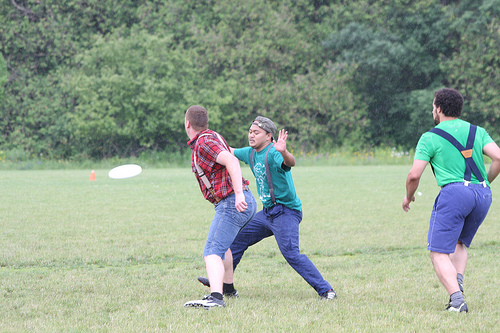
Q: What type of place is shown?
A: It is a field.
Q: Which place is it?
A: It is a field.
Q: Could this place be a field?
A: Yes, it is a field.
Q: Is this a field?
A: Yes, it is a field.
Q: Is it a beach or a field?
A: It is a field.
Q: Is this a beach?
A: No, it is a field.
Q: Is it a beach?
A: No, it is a field.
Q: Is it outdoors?
A: Yes, it is outdoors.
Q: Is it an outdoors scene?
A: Yes, it is outdoors.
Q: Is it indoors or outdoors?
A: It is outdoors.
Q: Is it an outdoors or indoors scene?
A: It is outdoors.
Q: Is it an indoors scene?
A: No, it is outdoors.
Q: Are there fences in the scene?
A: No, there are no fences.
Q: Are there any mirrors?
A: No, there are no mirrors.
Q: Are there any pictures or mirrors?
A: No, there are no mirrors or pictures.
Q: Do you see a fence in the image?
A: No, there are no fences.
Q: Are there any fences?
A: No, there are no fences.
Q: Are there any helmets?
A: No, there are no helmets.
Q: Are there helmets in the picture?
A: No, there are no helmets.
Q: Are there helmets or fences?
A: No, there are no helmets or fences.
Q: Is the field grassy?
A: Yes, the field is grassy.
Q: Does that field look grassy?
A: Yes, the field is grassy.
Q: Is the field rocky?
A: No, the field is grassy.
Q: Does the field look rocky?
A: No, the field is grassy.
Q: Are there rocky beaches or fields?
A: No, there is a field but it is grassy.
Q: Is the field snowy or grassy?
A: The field is grassy.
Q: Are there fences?
A: No, there are no fences.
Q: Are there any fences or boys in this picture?
A: No, there are no fences or boys.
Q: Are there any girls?
A: No, there are no girls.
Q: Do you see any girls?
A: No, there are no girls.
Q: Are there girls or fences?
A: No, there are no girls or fences.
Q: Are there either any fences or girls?
A: No, there are no girls or fences.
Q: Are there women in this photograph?
A: No, there are no women.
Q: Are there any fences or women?
A: No, there are no women or fences.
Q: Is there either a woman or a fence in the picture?
A: No, there are no women or fences.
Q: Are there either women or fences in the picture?
A: No, there are no women or fences.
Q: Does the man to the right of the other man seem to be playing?
A: Yes, the man is playing.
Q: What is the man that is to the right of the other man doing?
A: The man is playing.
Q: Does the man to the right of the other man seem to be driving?
A: No, the man is playing.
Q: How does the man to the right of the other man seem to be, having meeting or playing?
A: The man is playing.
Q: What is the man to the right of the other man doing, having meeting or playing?
A: The man is playing.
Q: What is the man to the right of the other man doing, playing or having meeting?
A: The man is playing.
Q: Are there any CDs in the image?
A: No, there are no cds.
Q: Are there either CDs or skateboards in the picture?
A: No, there are no CDs or skateboards.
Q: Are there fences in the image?
A: No, there are no fences.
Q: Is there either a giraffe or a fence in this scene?
A: No, there are no fences or giraffes.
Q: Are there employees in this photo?
A: No, there are no employees.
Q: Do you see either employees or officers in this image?
A: No, there are no employees or officers.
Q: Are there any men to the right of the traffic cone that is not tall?
A: Yes, there is a man to the right of the safety cone.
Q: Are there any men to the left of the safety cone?
A: No, the man is to the right of the safety cone.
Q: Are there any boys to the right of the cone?
A: No, there is a man to the right of the cone.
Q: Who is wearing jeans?
A: The man is wearing jeans.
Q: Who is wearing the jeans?
A: The man is wearing jeans.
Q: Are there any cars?
A: No, there are no cars.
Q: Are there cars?
A: No, there are no cars.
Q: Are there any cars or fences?
A: No, there are no cars or fences.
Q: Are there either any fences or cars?
A: No, there are no cars or fences.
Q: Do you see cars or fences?
A: No, there are no cars or fences.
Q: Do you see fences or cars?
A: No, there are no cars or fences.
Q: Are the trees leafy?
A: Yes, the trees are leafy.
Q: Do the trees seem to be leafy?
A: Yes, the trees are leafy.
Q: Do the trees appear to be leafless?
A: No, the trees are leafy.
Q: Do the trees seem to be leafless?
A: No, the trees are leafy.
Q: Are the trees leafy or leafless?
A: The trees are leafy.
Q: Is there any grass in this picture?
A: Yes, there is grass.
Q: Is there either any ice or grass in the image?
A: Yes, there is grass.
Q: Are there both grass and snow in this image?
A: No, there is grass but no snow.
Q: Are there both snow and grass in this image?
A: No, there is grass but no snow.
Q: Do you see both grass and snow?
A: No, there is grass but no snow.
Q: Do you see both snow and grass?
A: No, there is grass but no snow.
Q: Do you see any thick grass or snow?
A: Yes, there is thick grass.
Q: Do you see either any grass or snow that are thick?
A: Yes, the grass is thick.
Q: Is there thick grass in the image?
A: Yes, there is thick grass.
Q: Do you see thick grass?
A: Yes, there is thick grass.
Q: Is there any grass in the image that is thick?
A: Yes, there is grass that is thick.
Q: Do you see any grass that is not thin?
A: Yes, there is thick grass.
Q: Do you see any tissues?
A: No, there are no tissues.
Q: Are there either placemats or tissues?
A: No, there are no tissues or placemats.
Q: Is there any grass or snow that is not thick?
A: No, there is grass but it is thick.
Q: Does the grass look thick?
A: Yes, the grass is thick.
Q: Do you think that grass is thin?
A: No, the grass is thick.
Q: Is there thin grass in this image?
A: No, there is grass but it is thick.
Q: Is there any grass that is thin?
A: No, there is grass but it is thick.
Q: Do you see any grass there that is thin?
A: No, there is grass but it is thick.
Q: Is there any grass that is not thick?
A: No, there is grass but it is thick.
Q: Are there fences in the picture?
A: No, there are no fences.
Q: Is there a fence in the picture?
A: No, there are no fences.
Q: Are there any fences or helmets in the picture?
A: No, there are no fences or helmets.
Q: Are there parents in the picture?
A: No, there are no parents.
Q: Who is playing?
A: The man is playing.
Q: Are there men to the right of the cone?
A: Yes, there is a man to the right of the cone.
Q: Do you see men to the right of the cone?
A: Yes, there is a man to the right of the cone.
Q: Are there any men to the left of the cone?
A: No, the man is to the right of the cone.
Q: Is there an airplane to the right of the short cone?
A: No, there is a man to the right of the cone.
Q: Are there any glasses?
A: No, there are no glasses.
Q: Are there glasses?
A: No, there are no glasses.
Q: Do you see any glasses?
A: No, there are no glasses.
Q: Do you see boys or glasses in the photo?
A: No, there are no glasses or boys.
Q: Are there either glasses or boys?
A: No, there are no glasses or boys.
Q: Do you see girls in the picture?
A: No, there are no girls.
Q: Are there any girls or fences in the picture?
A: No, there are no girls or fences.